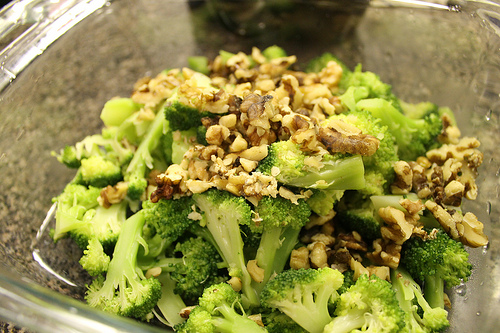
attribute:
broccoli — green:
[204, 91, 443, 298]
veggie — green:
[242, 62, 457, 246]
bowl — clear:
[45, 22, 112, 122]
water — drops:
[450, 278, 478, 296]